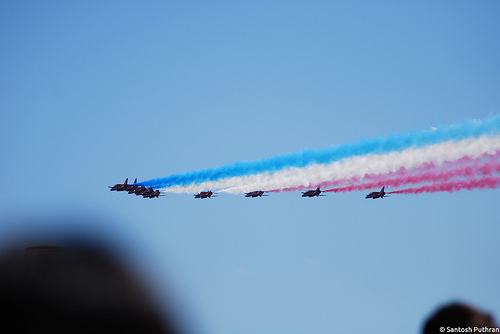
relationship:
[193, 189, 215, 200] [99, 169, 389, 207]
jets in formation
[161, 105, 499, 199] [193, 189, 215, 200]
smoke from jets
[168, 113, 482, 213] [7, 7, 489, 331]
clouds in sky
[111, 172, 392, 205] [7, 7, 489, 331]
jets in sky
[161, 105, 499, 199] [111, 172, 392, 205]
smoke behind jets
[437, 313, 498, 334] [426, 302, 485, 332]
writing in corner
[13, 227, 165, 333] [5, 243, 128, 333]
head of person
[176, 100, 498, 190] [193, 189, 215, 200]
streams behind jets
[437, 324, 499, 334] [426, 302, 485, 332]
writing in corner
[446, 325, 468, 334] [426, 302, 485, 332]
santosh in corner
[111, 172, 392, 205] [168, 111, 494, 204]
jets leaving trails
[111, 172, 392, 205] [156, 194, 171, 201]
jets have wings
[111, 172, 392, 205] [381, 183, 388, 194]
jets have tails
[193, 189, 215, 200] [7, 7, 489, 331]
jets in sky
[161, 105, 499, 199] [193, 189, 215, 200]
smoke coming out of jets